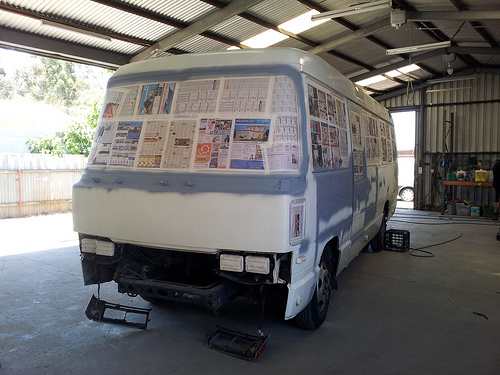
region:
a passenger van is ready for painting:
[69, 44, 401, 322]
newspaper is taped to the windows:
[89, 65, 404, 200]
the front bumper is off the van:
[75, 237, 296, 374]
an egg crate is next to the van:
[377, 224, 412, 257]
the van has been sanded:
[68, 62, 398, 260]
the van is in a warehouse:
[28, 4, 492, 371]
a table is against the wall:
[436, 160, 498, 222]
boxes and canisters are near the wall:
[437, 158, 494, 223]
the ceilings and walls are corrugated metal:
[4, 0, 499, 111]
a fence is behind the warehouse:
[3, 150, 85, 218]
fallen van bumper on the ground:
[200, 322, 279, 365]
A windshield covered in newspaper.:
[126, 89, 306, 169]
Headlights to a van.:
[83, 233, 281, 283]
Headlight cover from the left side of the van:
[206, 325, 267, 363]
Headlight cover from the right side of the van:
[90, 290, 150, 325]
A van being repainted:
[90, 97, 396, 322]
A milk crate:
[391, 212, 408, 259]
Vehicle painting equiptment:
[440, 151, 496, 225]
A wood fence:
[11, 161, 64, 219]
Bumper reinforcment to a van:
[121, 268, 227, 319]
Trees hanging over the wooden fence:
[38, 123, 88, 164]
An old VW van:
[30, 17, 466, 370]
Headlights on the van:
[66, 214, 305, 295]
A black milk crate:
[376, 225, 433, 267]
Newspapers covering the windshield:
[80, 75, 315, 187]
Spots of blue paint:
[313, 174, 366, 212]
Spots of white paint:
[73, 191, 293, 253]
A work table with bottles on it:
[429, 160, 498, 212]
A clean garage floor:
[364, 256, 463, 373]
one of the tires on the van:
[306, 251, 345, 340]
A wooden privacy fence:
[0, 154, 74, 221]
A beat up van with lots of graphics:
[75, 43, 419, 316]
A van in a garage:
[31, 8, 493, 373]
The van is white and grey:
[72, 45, 422, 319]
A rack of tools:
[412, 143, 498, 213]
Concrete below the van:
[333, 256, 492, 361]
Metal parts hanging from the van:
[82, 297, 264, 357]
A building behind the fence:
[0, 99, 93, 158]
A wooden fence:
[0, 156, 88, 210]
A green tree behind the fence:
[30, 105, 101, 154]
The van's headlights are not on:
[67, 231, 281, 288]